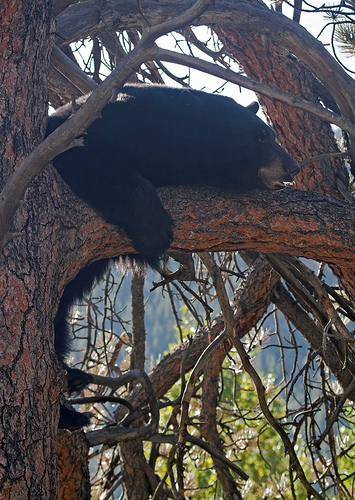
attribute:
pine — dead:
[11, 215, 350, 332]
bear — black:
[47, 83, 301, 428]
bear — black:
[38, 79, 303, 339]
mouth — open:
[256, 159, 297, 191]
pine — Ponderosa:
[0, 166, 353, 492]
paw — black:
[119, 181, 180, 262]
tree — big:
[221, 178, 286, 240]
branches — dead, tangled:
[63, 271, 320, 491]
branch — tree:
[115, 258, 277, 498]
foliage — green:
[227, 363, 259, 411]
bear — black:
[103, 89, 303, 206]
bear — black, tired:
[41, 72, 311, 266]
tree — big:
[76, 425, 219, 465]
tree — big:
[82, 35, 353, 256]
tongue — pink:
[270, 179, 286, 188]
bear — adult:
[48, 80, 304, 258]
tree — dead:
[2, 1, 93, 495]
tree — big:
[34, 386, 180, 477]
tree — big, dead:
[0, 1, 349, 498]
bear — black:
[124, 100, 282, 181]